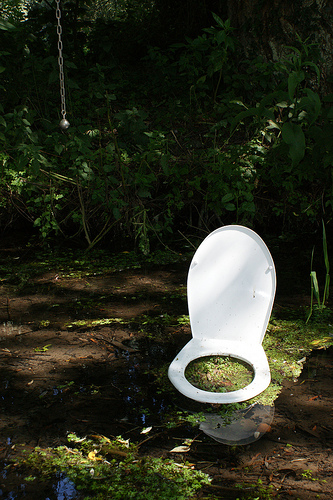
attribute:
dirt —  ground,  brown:
[10, 277, 141, 411]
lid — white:
[175, 231, 279, 405]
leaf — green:
[239, 198, 257, 216]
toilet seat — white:
[167, 223, 277, 403]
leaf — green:
[118, 198, 134, 209]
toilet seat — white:
[168, 339, 271, 401]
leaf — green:
[109, 202, 125, 220]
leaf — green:
[40, 1, 201, 261]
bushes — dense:
[46, 63, 277, 241]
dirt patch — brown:
[10, 270, 321, 499]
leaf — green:
[114, 144, 130, 163]